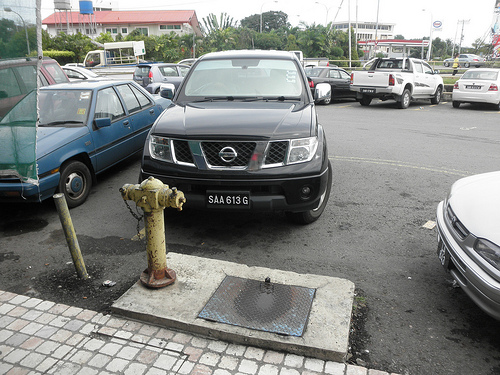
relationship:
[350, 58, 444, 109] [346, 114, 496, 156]
truck in lot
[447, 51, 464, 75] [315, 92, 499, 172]
person on road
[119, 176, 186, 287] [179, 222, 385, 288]
fire hydrant on ground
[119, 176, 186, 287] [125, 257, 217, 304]
fire hydrant on ground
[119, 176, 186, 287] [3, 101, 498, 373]
fire hydrant on ground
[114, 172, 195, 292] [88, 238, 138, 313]
fire hydrant on ground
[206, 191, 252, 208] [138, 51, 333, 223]
license plate on black suv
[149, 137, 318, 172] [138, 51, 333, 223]
grill on black suv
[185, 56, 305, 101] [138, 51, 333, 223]
windshield of black suv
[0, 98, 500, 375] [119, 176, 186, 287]
ground of fire hydrant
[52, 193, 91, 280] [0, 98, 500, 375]
metal rod on ground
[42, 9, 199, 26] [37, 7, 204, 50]
roof of building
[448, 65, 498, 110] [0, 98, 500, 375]
sedan in ground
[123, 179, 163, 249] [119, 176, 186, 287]
chain on fire hydrant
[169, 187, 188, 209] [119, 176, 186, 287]
cap on fire hydrant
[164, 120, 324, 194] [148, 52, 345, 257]
grill on car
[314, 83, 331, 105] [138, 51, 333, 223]
rearview mirror on black suv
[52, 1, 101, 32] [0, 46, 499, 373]
water towers behind parking lot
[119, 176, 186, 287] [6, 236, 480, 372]
fire hydrant on ground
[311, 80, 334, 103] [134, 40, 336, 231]
rearview mirror on vehicle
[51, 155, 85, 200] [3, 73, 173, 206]
black wheel on vehicle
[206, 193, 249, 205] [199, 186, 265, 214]
lettering on license plate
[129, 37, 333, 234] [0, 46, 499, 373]
black suv in parking lot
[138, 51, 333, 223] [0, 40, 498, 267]
black suv in parking lot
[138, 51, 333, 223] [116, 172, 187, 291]
black suv near fire hyrdrant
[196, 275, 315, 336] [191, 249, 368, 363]
drain over drain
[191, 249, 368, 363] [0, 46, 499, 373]
drain in parking lot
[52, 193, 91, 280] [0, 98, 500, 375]
metal rod in ground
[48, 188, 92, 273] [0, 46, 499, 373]
metal rod in parking lot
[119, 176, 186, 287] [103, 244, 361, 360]
fire hydrant on slab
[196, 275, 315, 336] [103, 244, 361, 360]
drain on slab